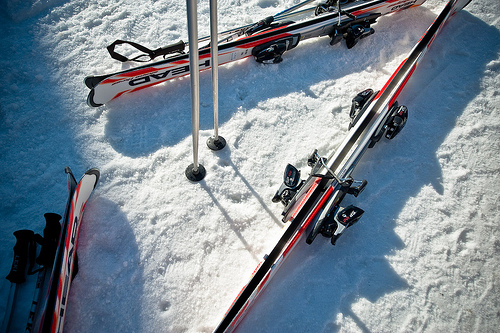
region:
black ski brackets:
[255, 157, 312, 199]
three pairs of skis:
[42, 39, 467, 309]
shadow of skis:
[261, 24, 493, 327]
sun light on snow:
[124, 167, 248, 284]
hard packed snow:
[400, 201, 487, 316]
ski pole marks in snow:
[145, 291, 183, 320]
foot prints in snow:
[415, 245, 487, 306]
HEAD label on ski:
[117, 52, 224, 92]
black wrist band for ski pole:
[105, 36, 170, 66]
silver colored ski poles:
[160, 18, 261, 180]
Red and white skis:
[216, 29, 438, 331]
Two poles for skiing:
[172, 0, 232, 186]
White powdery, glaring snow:
[130, 192, 221, 290]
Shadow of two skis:
[363, 78, 489, 310]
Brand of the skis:
[119, 51, 216, 100]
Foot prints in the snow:
[133, 208, 209, 314]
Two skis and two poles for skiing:
[4, 161, 111, 331]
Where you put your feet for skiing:
[269, 155, 376, 241]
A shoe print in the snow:
[77, 106, 166, 166]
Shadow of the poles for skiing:
[192, 159, 292, 262]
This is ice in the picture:
[446, 290, 492, 313]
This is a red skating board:
[170, 245, 291, 331]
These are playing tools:
[168, 64, 425, 325]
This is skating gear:
[276, 11, 428, 329]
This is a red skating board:
[8, 168, 130, 328]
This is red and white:
[1, 158, 126, 325]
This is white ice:
[95, 200, 190, 250]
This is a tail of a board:
[85, 25, 184, 204]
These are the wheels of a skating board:
[245, 0, 411, 230]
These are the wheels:
[241, 2, 416, 253]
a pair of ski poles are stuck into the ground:
[184, 1, 227, 181]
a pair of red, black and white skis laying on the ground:
[48, 166, 99, 328]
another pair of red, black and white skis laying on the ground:
[213, 1, 460, 331]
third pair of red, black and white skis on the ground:
[83, 0, 430, 108]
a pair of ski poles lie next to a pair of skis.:
[4, 210, 64, 330]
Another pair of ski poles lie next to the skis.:
[108, 5, 334, 62]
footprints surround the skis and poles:
[406, 222, 498, 326]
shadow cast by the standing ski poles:
[198, 175, 284, 251]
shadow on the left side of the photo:
[11, 32, 69, 204]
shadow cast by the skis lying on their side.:
[105, 45, 401, 157]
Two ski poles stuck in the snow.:
[167, 0, 257, 190]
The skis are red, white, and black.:
[215, 0, 430, 330]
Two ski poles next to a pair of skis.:
[70, 0, 366, 120]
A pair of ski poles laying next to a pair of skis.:
[0, 157, 110, 327]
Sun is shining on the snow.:
[146, 195, 231, 260]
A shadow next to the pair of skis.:
[286, 76, 487, 327]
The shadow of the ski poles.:
[176, 135, 286, 257]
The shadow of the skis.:
[101, 13, 452, 169]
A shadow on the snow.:
[10, 96, 50, 161]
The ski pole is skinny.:
[180, 0, 207, 196]